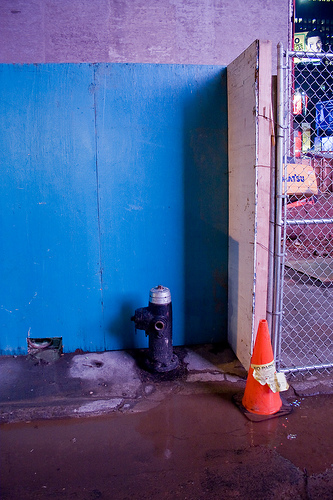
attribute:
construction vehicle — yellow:
[281, 162, 317, 195]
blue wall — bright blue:
[1, 62, 228, 351]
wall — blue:
[33, 36, 213, 285]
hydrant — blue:
[121, 279, 201, 382]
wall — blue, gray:
[86, 17, 204, 50]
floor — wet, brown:
[3, 340, 331, 496]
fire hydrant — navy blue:
[129, 284, 184, 377]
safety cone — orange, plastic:
[240, 319, 283, 415]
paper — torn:
[249, 356, 290, 392]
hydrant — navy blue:
[129, 285, 177, 374]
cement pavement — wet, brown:
[0, 352, 332, 495]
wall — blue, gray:
[11, 57, 227, 336]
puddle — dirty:
[0, 354, 155, 424]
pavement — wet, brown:
[43, 396, 228, 468]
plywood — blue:
[93, 58, 228, 350]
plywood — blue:
[2, 59, 100, 352]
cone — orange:
[244, 320, 288, 419]